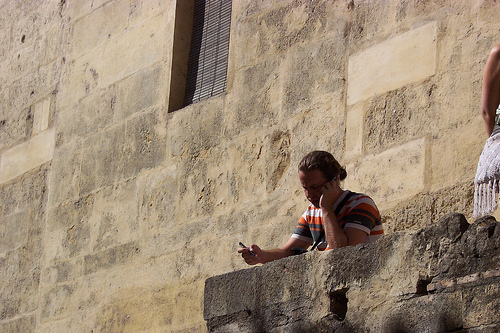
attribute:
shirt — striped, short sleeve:
[292, 186, 385, 249]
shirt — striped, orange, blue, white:
[301, 192, 381, 241]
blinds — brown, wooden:
[185, 0, 231, 105]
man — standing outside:
[180, 122, 394, 331]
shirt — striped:
[288, 188, 380, 250]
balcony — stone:
[203, 213, 498, 332]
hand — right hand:
[238, 242, 265, 265]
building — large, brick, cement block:
[1, 2, 499, 332]